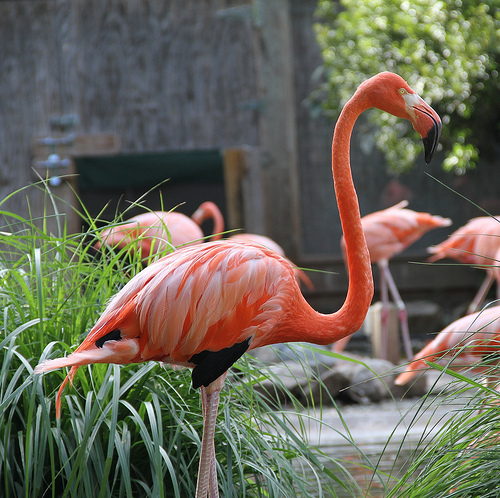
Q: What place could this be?
A: It is a zoo.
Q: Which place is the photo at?
A: It is at the zoo.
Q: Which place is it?
A: It is a zoo.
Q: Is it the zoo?
A: Yes, it is the zoo.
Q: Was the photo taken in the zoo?
A: Yes, it was taken in the zoo.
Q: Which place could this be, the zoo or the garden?
A: It is the zoo.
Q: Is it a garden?
A: No, it is a zoo.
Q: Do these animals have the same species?
A: No, there are both flamingoes and birds.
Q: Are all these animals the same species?
A: No, there are both flamingoes and birds.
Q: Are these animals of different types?
A: Yes, they are flamingoes and birds.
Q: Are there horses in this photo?
A: No, there are no horses.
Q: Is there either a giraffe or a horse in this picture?
A: No, there are no horses or giraffes.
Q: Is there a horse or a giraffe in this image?
A: No, there are no horses or giraffes.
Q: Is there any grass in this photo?
A: Yes, there is grass.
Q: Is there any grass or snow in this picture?
A: Yes, there is grass.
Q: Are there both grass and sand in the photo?
A: No, there is grass but no sand.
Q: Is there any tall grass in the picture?
A: Yes, there is tall grass.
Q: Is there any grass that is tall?
A: Yes, there is grass that is tall.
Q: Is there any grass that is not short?
A: Yes, there is tall grass.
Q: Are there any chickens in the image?
A: No, there are no chickens.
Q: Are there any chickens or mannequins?
A: No, there are no chickens or mannequins.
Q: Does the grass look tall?
A: Yes, the grass is tall.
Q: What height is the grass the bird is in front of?
A: The grass is tall.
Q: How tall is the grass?
A: The grass is tall.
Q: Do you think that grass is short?
A: No, the grass is tall.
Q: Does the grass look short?
A: No, the grass is tall.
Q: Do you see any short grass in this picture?
A: No, there is grass but it is tall.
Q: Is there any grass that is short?
A: No, there is grass but it is tall.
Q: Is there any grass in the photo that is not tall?
A: No, there is grass but it is tall.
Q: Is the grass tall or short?
A: The grass is tall.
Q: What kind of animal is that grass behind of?
A: The grass is behind the bird.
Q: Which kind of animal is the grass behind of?
A: The grass is behind the bird.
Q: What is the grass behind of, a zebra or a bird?
A: The grass is behind a bird.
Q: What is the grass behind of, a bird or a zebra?
A: The grass is behind a bird.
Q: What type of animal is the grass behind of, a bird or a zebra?
A: The grass is behind a bird.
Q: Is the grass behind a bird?
A: Yes, the grass is behind a bird.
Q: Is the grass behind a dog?
A: No, the grass is behind a bird.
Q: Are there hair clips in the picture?
A: No, there are no hair clips.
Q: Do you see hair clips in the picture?
A: No, there are no hair clips.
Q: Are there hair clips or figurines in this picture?
A: No, there are no hair clips or figurines.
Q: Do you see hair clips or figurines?
A: No, there are no hair clips or figurines.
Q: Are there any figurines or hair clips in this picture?
A: No, there are no hair clips or figurines.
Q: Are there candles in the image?
A: No, there are no candles.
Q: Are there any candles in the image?
A: No, there are no candles.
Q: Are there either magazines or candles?
A: No, there are no candles or magazines.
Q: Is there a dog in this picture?
A: No, there are no dogs.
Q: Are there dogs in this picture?
A: No, there are no dogs.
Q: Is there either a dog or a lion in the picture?
A: No, there are no dogs or lions.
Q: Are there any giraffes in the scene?
A: No, there are no giraffes.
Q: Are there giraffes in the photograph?
A: No, there are no giraffes.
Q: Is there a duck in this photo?
A: No, there are no ducks.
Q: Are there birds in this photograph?
A: Yes, there is a bird.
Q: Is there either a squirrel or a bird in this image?
A: Yes, there is a bird.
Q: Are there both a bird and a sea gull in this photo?
A: No, there is a bird but no seagulls.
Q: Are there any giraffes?
A: No, there are no giraffes.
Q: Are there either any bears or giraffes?
A: No, there are no giraffes or bears.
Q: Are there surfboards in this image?
A: No, there are no surfboards.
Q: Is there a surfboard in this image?
A: No, there are no surfboards.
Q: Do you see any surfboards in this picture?
A: No, there are no surfboards.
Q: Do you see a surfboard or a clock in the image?
A: No, there are no surfboards or clocks.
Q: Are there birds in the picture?
A: Yes, there is a bird.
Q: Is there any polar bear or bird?
A: Yes, there is a bird.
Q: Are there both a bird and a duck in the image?
A: No, there is a bird but no ducks.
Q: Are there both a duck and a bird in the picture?
A: No, there is a bird but no ducks.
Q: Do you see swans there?
A: No, there are no swans.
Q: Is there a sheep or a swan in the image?
A: No, there are no swans or sheep.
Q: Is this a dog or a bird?
A: This is a bird.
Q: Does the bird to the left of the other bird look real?
A: Yes, the bird is real.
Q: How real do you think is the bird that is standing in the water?
A: The bird is real.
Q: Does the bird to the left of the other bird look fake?
A: No, the bird is real.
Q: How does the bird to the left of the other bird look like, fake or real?
A: The bird is real.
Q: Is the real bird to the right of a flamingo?
A: No, the bird is to the left of a flamingo.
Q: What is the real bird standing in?
A: The bird is standing in the water.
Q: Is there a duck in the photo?
A: No, there are no ducks.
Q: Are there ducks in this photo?
A: No, there are no ducks.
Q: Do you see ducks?
A: No, there are no ducks.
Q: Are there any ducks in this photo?
A: No, there are no ducks.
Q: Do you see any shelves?
A: No, there are no shelves.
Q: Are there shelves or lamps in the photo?
A: No, there are no shelves or lamps.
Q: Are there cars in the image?
A: No, there are no cars.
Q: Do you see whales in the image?
A: No, there are no whales.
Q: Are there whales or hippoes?
A: No, there are no whales or hippoes.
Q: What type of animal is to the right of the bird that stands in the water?
A: The animal is a flamingo.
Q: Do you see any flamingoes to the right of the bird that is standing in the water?
A: Yes, there is a flamingo to the right of the bird.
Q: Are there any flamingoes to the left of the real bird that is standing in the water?
A: No, the flamingo is to the right of the bird.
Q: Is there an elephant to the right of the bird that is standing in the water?
A: No, there is a flamingo to the right of the bird.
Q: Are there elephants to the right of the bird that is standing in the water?
A: No, there is a flamingo to the right of the bird.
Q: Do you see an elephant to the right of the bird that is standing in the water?
A: No, there is a flamingo to the right of the bird.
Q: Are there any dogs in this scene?
A: No, there are no dogs.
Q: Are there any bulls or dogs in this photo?
A: No, there are no dogs or bulls.